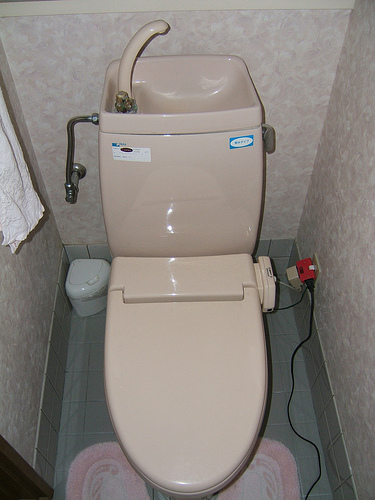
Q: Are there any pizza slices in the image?
A: No, there are no pizza slices.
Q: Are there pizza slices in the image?
A: No, there are no pizza slices.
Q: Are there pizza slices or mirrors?
A: No, there are no pizza slices or mirrors.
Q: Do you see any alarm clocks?
A: No, there are no alarm clocks.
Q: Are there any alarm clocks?
A: No, there are no alarm clocks.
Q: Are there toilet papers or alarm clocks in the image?
A: No, there are no alarm clocks or toilet papers.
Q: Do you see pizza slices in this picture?
A: No, there are no pizza slices.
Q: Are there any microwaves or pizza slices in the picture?
A: No, there are no pizza slices or microwaves.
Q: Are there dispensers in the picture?
A: No, there are no dispensers.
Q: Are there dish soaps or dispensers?
A: No, there are no dispensers or dish soaps.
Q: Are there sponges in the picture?
A: No, there are no sponges.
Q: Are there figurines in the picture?
A: No, there are no figurines.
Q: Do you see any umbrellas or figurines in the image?
A: No, there are no figurines or umbrellas.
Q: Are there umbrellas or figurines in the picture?
A: No, there are no figurines or umbrellas.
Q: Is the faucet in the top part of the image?
A: Yes, the faucet is in the top of the image.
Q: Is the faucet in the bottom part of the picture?
A: No, the faucet is in the top of the image.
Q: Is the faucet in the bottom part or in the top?
A: The faucet is in the top of the image.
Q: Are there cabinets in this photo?
A: No, there are no cabinets.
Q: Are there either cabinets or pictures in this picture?
A: No, there are no cabinets or pictures.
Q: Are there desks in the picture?
A: No, there are no desks.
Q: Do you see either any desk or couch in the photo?
A: No, there are no desks or couches.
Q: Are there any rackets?
A: No, there are no rackets.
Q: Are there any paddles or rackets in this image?
A: No, there are no rackets or paddles.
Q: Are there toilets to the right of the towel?
A: Yes, there is a toilet to the right of the towel.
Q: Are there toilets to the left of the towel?
A: No, the toilet is to the right of the towel.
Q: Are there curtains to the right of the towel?
A: No, there is a toilet to the right of the towel.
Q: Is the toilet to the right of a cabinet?
A: No, the toilet is to the right of the towel.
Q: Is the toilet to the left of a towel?
A: No, the toilet is to the right of a towel.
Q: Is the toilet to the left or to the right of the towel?
A: The toilet is to the right of the towel.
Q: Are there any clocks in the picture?
A: No, there are no clocks.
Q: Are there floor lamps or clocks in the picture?
A: No, there are no clocks or floor lamps.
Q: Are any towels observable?
A: Yes, there is a towel.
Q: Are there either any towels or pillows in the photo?
A: Yes, there is a towel.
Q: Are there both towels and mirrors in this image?
A: No, there is a towel but no mirrors.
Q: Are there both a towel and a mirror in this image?
A: No, there is a towel but no mirrors.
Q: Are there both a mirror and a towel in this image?
A: No, there is a towel but no mirrors.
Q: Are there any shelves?
A: No, there are no shelves.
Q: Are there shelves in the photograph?
A: No, there are no shelves.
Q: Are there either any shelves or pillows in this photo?
A: No, there are no shelves or pillows.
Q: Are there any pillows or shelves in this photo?
A: No, there are no shelves or pillows.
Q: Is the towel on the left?
A: Yes, the towel is on the left of the image.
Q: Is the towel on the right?
A: No, the towel is on the left of the image.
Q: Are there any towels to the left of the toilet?
A: Yes, there is a towel to the left of the toilet.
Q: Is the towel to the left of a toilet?
A: Yes, the towel is to the left of a toilet.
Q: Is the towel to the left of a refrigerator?
A: No, the towel is to the left of a toilet.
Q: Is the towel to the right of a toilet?
A: No, the towel is to the left of a toilet.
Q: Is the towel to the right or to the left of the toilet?
A: The towel is to the left of the toilet.